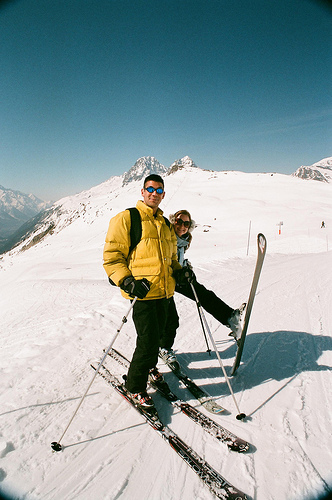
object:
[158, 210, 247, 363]
person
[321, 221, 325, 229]
person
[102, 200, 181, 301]
jacket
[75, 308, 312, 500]
ski marks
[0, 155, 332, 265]
rocky terrain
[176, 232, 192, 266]
jacket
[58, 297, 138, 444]
pole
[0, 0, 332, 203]
sky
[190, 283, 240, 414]
pole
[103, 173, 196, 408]
statue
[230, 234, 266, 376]
ski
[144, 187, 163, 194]
goggles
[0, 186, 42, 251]
mountain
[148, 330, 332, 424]
shadow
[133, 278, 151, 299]
hand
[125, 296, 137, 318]
handle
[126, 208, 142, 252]
strap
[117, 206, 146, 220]
shoulder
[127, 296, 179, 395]
black pants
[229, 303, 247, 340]
foot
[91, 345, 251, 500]
ski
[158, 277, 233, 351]
pants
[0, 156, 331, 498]
snow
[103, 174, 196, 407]
man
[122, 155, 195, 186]
outcrops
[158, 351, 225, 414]
ski